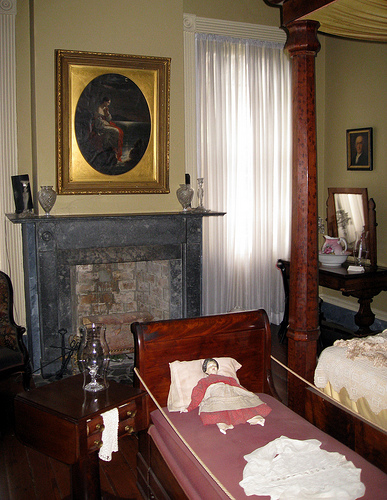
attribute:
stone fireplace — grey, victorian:
[57, 241, 190, 370]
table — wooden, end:
[273, 242, 384, 333]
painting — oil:
[76, 73, 151, 172]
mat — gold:
[53, 50, 171, 193]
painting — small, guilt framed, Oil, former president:
[345, 128, 375, 170]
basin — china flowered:
[319, 253, 349, 267]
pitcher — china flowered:
[320, 232, 348, 253]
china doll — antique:
[174, 348, 271, 441]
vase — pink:
[315, 232, 350, 272]